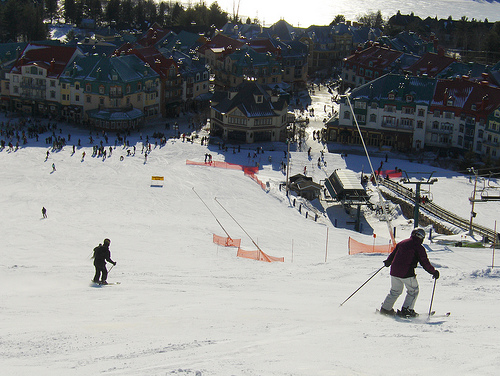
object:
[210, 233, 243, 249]
netting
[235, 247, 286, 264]
netting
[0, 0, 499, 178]
town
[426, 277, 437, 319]
ski pole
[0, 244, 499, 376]
hill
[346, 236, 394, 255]
fence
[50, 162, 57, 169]
skiers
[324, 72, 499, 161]
buildings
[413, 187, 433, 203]
chair lift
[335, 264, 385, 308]
poles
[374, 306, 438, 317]
skis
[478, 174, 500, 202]
chair lift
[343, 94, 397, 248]
wires up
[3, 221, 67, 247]
air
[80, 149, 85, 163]
people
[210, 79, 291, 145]
building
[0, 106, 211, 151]
shadow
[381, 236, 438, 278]
sweater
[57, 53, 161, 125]
cabins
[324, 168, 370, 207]
ski station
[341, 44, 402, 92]
cabin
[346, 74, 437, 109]
roof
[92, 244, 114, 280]
suit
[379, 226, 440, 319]
person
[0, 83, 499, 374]
snow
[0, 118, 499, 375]
ground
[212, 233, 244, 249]
barrier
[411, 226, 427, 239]
helmet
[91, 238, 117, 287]
person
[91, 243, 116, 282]
clothes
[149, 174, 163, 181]
flag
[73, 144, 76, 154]
people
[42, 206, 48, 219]
person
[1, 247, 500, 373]
ski slope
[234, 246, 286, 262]
barriers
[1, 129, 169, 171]
crowd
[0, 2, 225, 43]
trees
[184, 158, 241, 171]
barrier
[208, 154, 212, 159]
people